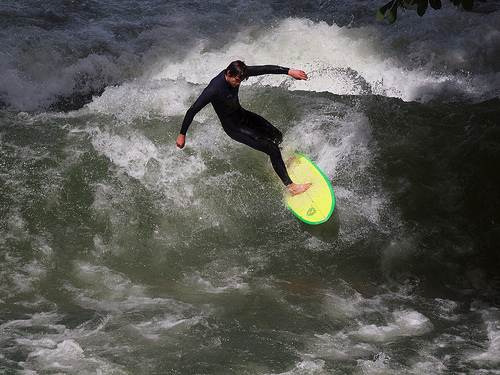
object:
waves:
[0, 0, 499, 290]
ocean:
[0, 0, 500, 375]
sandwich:
[315, 26, 405, 135]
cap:
[87, 75, 187, 121]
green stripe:
[279, 152, 335, 225]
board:
[270, 149, 335, 225]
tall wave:
[1, 0, 498, 302]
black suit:
[177, 64, 292, 185]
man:
[175, 60, 313, 197]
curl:
[0, 73, 498, 163]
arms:
[179, 87, 219, 136]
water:
[0, 3, 499, 370]